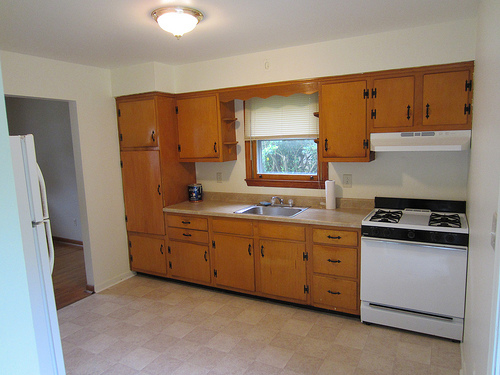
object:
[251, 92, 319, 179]
window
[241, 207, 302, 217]
sink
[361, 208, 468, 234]
stove top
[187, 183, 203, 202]
coffee machine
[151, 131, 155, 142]
cabinet handle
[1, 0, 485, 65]
ceiling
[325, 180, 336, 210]
paper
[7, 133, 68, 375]
fridge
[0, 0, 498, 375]
kitchen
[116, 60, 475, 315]
cabinet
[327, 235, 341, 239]
knob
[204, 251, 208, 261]
knob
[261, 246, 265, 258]
knob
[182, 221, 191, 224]
knob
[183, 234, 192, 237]
knob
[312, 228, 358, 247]
drawer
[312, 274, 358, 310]
drawer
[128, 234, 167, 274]
drawer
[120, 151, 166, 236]
drawer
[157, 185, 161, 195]
knob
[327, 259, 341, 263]
knob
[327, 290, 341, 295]
knob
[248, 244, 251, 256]
knob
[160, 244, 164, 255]
knob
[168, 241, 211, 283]
drawer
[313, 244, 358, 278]
drawer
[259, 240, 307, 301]
drawer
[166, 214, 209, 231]
drawer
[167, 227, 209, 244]
drawer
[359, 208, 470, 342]
oven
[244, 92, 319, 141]
blinds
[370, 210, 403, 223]
burner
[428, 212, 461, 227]
burner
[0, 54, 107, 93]
wall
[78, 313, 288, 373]
floor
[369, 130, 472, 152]
exhaust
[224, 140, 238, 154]
shelves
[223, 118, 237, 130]
shelves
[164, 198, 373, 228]
countertop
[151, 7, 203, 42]
dome light